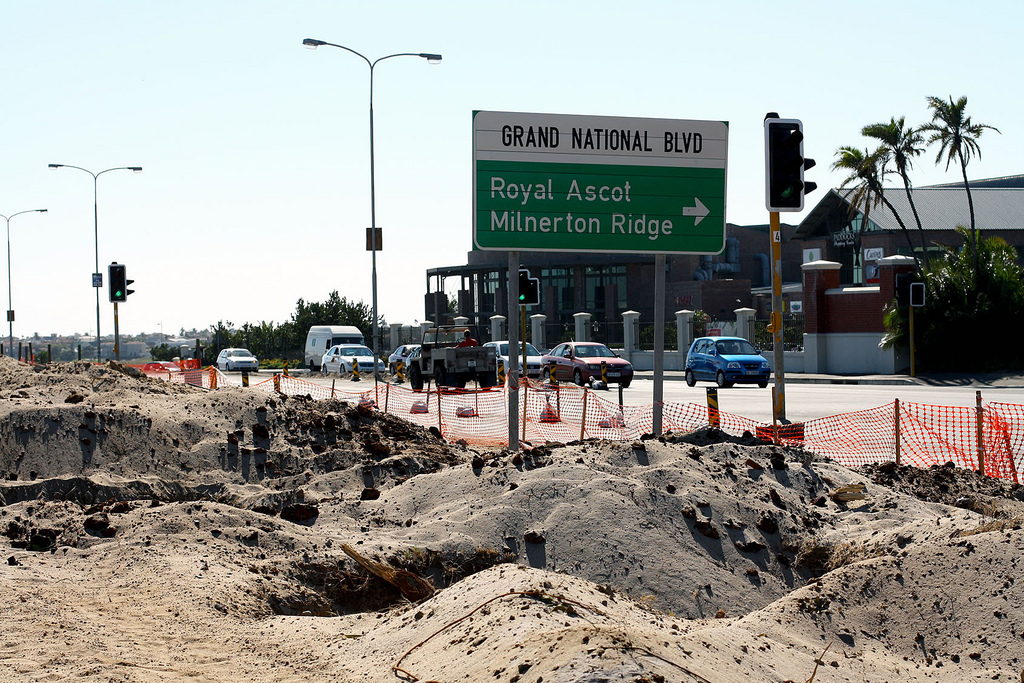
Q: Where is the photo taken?
A: Along Grand National Blvd.